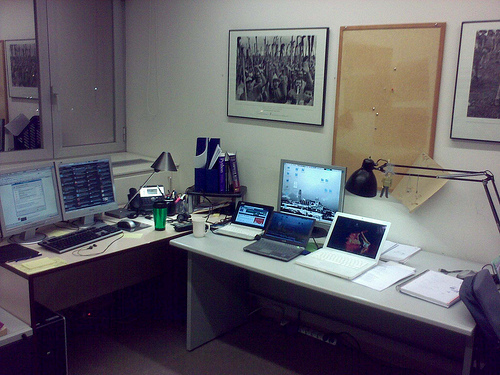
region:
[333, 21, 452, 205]
brown board hanging on a wall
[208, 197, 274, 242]
black laptop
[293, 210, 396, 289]
white laptop on a desk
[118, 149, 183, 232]
black desk lamp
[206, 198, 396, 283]
three laptops on a desk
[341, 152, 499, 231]
black lamp extended over a desk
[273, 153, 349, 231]
monitor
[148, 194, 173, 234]
black and green cup on a desk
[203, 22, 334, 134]
black and white art on a wall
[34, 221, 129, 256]
black keyboard on a desk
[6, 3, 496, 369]
an office with many electronic devices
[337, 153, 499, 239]
a black lamp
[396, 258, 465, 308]
a spiral notepad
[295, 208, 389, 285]
white laptop computer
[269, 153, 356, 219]
computer monitor near wall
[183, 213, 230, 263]
white mug on desk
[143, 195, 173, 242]
a green and black travel mug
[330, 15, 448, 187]
a bulletin board on the wall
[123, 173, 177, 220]
a telephone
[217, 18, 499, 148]
framed images on either side of bulletin board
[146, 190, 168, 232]
a green coffee mug on the desk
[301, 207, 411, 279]
a white laptop computer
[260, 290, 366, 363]
extension cords on the ground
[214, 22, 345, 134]
a picture on the wall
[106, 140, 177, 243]
a desk lamp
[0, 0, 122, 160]
a mirror on the wall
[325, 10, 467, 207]
an empty corkboard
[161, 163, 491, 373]
a white desk with electronics on it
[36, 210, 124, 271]
a keyboard for the computer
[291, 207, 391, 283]
A white open laptop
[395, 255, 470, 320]
A notebook sitting on the desk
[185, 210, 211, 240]
A white coffee cup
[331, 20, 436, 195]
A cork message board on the wall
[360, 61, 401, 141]
Pins pushed into the cork board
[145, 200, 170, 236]
A green drinking cup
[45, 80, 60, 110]
The silver lever on the window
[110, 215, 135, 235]
A black and silver mouse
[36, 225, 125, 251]
The keyboard of the desktop computer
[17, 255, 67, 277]
Yellow sticky tab note papers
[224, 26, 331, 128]
a black and white picture frame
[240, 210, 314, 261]
a gray laptop computer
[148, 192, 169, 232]
a tall coffee mug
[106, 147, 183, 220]
a gray desktop lamp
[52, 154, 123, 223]
a gray computer monitor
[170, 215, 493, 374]
a gray computer desk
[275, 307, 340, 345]
a white power cord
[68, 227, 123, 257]
black ear phones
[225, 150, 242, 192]
a purple book